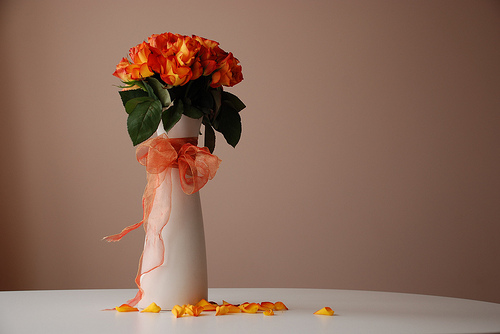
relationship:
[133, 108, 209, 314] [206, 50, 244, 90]
vase has flower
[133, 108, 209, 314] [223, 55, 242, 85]
vase has flower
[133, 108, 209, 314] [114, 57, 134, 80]
vase has flower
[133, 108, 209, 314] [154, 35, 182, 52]
vase has flower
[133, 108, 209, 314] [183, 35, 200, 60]
vase has flower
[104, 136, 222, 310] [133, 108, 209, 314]
ribbon on vase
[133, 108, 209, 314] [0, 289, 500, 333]
vase on table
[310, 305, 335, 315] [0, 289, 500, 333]
petal on table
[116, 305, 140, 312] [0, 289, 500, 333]
petal on table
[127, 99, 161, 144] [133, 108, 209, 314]
leaf in vase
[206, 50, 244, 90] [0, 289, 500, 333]
flower on table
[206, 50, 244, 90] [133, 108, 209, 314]
flower in vase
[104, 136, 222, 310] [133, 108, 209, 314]
ribbon tied around vase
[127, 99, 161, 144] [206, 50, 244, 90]
leaf from flower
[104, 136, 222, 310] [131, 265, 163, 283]
ribbon sides have wire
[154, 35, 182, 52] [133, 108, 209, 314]
flower in vase